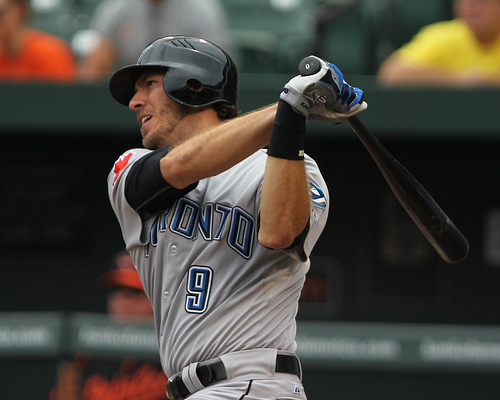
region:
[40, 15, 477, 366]
Batter takes a swing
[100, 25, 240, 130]
batter's protective helmet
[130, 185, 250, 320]
player's team and number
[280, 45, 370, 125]
batting glove on both hands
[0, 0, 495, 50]
out of focus crowd in the background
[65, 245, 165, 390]
player on the opposing team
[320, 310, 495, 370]
railing of the dugout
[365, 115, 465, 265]
player's black bat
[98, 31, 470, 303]
right handed batter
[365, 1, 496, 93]
man watching the game from the stands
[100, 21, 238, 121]
baseball helmet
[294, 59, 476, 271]
a black baseball bat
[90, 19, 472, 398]
a baseball batter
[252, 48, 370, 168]
a batters glove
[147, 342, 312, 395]
a black belt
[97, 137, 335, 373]
a baseball uniform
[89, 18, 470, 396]
baseball player swinging the bat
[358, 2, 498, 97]
audience behind the stadium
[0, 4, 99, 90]
audience wearing a orange shirt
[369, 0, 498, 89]
person is wearing a yellow shirt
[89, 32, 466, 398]
a baseball player holding a black bat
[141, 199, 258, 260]
blue lettering on a grey uniform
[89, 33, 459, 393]
a man swinging a black baseball bat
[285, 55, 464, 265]
a black baseball bat in a man's hands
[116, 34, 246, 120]
shiny black helmet of the baseball player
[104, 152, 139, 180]
red logo on the sleeve of the baseball player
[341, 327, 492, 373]
white lettering on the green fence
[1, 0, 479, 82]
several fans in the stands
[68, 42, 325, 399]
a baseball player wearing a grey uniform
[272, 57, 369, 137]
the baseball player's blue and grey gloves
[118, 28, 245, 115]
black helmet on player's head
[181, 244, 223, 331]
blue number nine on grey top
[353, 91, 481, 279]
black bat over man's shoulder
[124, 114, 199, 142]
beard on man's face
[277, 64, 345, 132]
batting glove on man's hand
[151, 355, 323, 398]
black belt on grey pants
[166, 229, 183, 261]
grey button on man's top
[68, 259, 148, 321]
blurry spectator in background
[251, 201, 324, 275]
mans bent elbow in photo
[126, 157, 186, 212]
black bottom of sleeve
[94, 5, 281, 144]
the helmet is black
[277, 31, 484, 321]
the bat is black